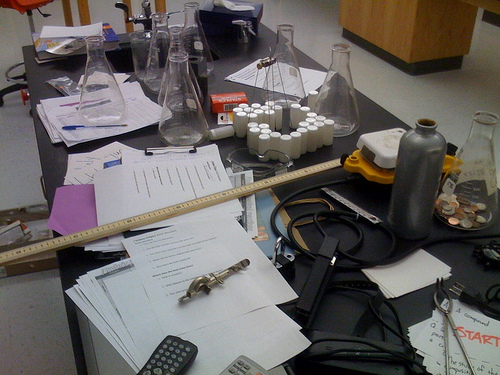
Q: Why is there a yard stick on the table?
A: To measure.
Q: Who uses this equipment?
A: Chemists.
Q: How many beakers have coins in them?
A: 1.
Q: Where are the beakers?
A: On the table.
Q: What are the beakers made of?
A: Glass.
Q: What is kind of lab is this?
A: Chemistry lab.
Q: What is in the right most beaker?
A: Coins.